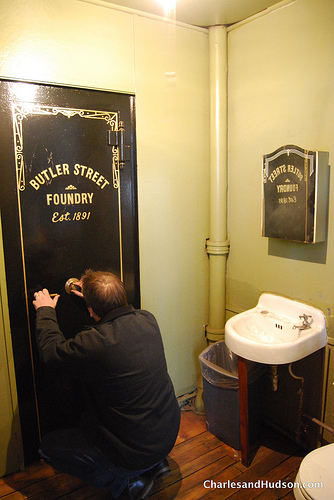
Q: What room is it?
A: It is a bathroom.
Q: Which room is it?
A: It is a bathroom.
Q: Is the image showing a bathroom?
A: Yes, it is showing a bathroom.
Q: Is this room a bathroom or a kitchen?
A: It is a bathroom.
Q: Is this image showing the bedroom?
A: No, the picture is showing the bathroom.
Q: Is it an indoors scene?
A: Yes, it is indoors.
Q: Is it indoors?
A: Yes, it is indoors.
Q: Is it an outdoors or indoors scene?
A: It is indoors.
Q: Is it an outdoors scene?
A: No, it is indoors.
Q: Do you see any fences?
A: No, there are no fences.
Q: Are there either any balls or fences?
A: No, there are no fences or balls.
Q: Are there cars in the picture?
A: No, there are no cars.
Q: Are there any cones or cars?
A: No, there are no cars or cones.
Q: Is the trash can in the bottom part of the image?
A: Yes, the trash can is in the bottom of the image.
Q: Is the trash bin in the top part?
A: No, the trash bin is in the bottom of the image.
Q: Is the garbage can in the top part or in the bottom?
A: The garbage can is in the bottom of the image.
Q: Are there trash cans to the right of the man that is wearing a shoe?
A: Yes, there is a trash can to the right of the man.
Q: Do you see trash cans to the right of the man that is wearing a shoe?
A: Yes, there is a trash can to the right of the man.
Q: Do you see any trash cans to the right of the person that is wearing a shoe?
A: Yes, there is a trash can to the right of the man.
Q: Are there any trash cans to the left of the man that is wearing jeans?
A: No, the trash can is to the right of the man.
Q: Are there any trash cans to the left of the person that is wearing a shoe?
A: No, the trash can is to the right of the man.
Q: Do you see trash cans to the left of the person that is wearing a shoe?
A: No, the trash can is to the right of the man.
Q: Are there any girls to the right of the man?
A: No, there is a trash can to the right of the man.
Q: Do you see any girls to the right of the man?
A: No, there is a trash can to the right of the man.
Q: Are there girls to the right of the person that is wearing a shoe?
A: No, there is a trash can to the right of the man.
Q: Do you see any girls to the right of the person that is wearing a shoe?
A: No, there is a trash can to the right of the man.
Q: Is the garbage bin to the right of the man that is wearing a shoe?
A: Yes, the garbage bin is to the right of the man.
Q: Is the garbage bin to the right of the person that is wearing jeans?
A: Yes, the garbage bin is to the right of the man.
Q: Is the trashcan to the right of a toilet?
A: No, the trashcan is to the right of the man.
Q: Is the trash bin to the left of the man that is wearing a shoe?
A: No, the trash bin is to the right of the man.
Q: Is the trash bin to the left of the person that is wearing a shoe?
A: No, the trash bin is to the right of the man.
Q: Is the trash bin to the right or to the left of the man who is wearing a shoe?
A: The trash bin is to the right of the man.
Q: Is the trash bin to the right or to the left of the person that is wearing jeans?
A: The trash bin is to the right of the man.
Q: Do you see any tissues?
A: No, there are no tissues.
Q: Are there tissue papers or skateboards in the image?
A: No, there are no tissue papers or skateboards.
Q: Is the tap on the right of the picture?
A: Yes, the tap is on the right of the image.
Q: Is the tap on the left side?
A: No, the tap is on the right of the image.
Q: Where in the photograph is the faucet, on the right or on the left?
A: The faucet is on the right of the image.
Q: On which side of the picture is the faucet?
A: The faucet is on the right of the image.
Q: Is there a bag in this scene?
A: Yes, there is a bag.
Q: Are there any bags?
A: Yes, there is a bag.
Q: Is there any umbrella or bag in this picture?
A: Yes, there is a bag.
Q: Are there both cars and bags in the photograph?
A: No, there is a bag but no cars.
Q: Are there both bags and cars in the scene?
A: No, there is a bag but no cars.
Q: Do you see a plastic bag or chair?
A: Yes, there is a plastic bag.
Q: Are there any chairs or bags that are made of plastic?
A: Yes, the bag is made of plastic.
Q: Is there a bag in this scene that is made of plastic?
A: Yes, there is a bag that is made of plastic.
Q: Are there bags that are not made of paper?
A: Yes, there is a bag that is made of plastic.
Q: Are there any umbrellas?
A: No, there are no umbrellas.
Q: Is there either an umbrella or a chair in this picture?
A: No, there are no umbrellas or chairs.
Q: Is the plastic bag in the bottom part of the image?
A: Yes, the bag is in the bottom of the image.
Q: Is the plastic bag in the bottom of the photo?
A: Yes, the bag is in the bottom of the image.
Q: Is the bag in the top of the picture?
A: No, the bag is in the bottom of the image.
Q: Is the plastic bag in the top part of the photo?
A: No, the bag is in the bottom of the image.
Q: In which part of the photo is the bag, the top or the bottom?
A: The bag is in the bottom of the image.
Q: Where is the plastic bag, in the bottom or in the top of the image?
A: The bag is in the bottom of the image.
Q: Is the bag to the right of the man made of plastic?
A: Yes, the bag is made of plastic.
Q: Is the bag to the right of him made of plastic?
A: Yes, the bag is made of plastic.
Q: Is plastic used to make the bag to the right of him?
A: Yes, the bag is made of plastic.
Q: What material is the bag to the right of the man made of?
A: The bag is made of plastic.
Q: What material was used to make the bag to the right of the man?
A: The bag is made of plastic.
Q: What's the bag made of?
A: The bag is made of plastic.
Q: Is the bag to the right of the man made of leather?
A: No, the bag is made of plastic.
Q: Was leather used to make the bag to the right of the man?
A: No, the bag is made of plastic.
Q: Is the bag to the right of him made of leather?
A: No, the bag is made of plastic.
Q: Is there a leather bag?
A: No, there is a bag but it is made of plastic.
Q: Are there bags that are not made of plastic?
A: No, there is a bag but it is made of plastic.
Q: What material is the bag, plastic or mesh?
A: The bag is made of plastic.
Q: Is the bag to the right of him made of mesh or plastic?
A: The bag is made of plastic.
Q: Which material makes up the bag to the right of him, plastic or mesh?
A: The bag is made of plastic.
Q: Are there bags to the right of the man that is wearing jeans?
A: Yes, there is a bag to the right of the man.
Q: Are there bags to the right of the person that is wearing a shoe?
A: Yes, there is a bag to the right of the man.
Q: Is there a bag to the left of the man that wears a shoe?
A: No, the bag is to the right of the man.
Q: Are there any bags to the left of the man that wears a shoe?
A: No, the bag is to the right of the man.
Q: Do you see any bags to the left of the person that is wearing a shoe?
A: No, the bag is to the right of the man.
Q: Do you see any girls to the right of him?
A: No, there is a bag to the right of the man.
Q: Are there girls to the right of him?
A: No, there is a bag to the right of the man.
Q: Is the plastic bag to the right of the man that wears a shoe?
A: Yes, the bag is to the right of the man.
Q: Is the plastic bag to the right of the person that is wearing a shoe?
A: Yes, the bag is to the right of the man.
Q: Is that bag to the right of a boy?
A: No, the bag is to the right of the man.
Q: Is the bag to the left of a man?
A: No, the bag is to the right of a man.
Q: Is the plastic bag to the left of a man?
A: No, the bag is to the right of a man.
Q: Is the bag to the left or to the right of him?
A: The bag is to the right of the man.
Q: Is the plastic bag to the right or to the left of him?
A: The bag is to the right of the man.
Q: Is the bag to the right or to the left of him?
A: The bag is to the right of the man.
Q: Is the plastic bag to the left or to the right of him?
A: The bag is to the right of the man.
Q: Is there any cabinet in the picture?
A: Yes, there is a cabinet.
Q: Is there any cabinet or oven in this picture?
A: Yes, there is a cabinet.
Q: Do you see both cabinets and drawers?
A: No, there is a cabinet but no drawers.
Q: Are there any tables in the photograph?
A: No, there are no tables.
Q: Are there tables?
A: No, there are no tables.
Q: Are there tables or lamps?
A: No, there are no tables or lamps.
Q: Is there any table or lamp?
A: No, there are no tables or lamps.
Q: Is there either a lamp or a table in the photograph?
A: No, there are no tables or lamps.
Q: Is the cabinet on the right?
A: Yes, the cabinet is on the right of the image.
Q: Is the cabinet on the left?
A: No, the cabinet is on the right of the image.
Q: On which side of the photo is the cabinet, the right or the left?
A: The cabinet is on the right of the image.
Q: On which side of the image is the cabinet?
A: The cabinet is on the right of the image.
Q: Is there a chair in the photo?
A: No, there are no chairs.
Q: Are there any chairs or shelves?
A: No, there are no chairs or shelves.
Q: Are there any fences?
A: No, there are no fences.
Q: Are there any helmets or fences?
A: No, there are no fences or helmets.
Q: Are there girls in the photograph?
A: No, there are no girls.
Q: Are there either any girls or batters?
A: No, there are no girls or batters.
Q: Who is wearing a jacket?
A: The man is wearing a jacket.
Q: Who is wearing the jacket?
A: The man is wearing a jacket.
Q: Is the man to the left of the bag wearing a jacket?
A: Yes, the man is wearing a jacket.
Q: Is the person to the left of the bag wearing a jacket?
A: Yes, the man is wearing a jacket.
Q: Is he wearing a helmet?
A: No, the man is wearing a jacket.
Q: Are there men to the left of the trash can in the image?
A: Yes, there is a man to the left of the trash can.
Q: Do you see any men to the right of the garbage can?
A: No, the man is to the left of the garbage can.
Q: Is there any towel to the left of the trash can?
A: No, there is a man to the left of the trash can.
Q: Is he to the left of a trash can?
A: Yes, the man is to the left of a trash can.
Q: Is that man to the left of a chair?
A: No, the man is to the left of a trash can.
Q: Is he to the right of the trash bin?
A: No, the man is to the left of the trash bin.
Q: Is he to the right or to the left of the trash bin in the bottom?
A: The man is to the left of the garbage bin.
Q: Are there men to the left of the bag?
A: Yes, there is a man to the left of the bag.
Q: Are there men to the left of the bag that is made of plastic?
A: Yes, there is a man to the left of the bag.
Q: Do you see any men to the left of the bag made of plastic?
A: Yes, there is a man to the left of the bag.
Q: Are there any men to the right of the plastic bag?
A: No, the man is to the left of the bag.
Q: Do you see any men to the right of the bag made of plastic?
A: No, the man is to the left of the bag.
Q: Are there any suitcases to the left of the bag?
A: No, there is a man to the left of the bag.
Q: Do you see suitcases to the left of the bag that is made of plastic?
A: No, there is a man to the left of the bag.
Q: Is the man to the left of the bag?
A: Yes, the man is to the left of the bag.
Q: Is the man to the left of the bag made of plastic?
A: Yes, the man is to the left of the bag.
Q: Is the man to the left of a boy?
A: No, the man is to the left of the bag.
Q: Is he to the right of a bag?
A: No, the man is to the left of a bag.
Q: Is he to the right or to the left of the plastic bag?
A: The man is to the left of the bag.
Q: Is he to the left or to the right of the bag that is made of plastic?
A: The man is to the left of the bag.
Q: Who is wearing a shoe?
A: The man is wearing a shoe.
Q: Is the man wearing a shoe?
A: Yes, the man is wearing a shoe.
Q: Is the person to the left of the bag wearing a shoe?
A: Yes, the man is wearing a shoe.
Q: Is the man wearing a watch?
A: No, the man is wearing a shoe.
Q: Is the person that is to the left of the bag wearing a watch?
A: No, the man is wearing a shoe.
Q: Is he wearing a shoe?
A: Yes, the man is wearing a shoe.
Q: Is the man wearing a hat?
A: No, the man is wearing a shoe.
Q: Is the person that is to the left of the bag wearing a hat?
A: No, the man is wearing a shoe.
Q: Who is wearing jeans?
A: The man is wearing jeans.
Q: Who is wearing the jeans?
A: The man is wearing jeans.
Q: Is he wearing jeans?
A: Yes, the man is wearing jeans.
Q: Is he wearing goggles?
A: No, the man is wearing jeans.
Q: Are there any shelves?
A: No, there are no shelves.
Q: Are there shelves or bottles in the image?
A: No, there are no shelves or bottles.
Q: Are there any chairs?
A: No, there are no chairs.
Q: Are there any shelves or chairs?
A: No, there are no chairs or shelves.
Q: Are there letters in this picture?
A: Yes, there are letters.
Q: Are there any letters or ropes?
A: Yes, there are letters.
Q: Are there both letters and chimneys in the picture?
A: No, there are letters but no chimneys.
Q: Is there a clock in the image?
A: No, there are no clocks.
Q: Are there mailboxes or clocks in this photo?
A: No, there are no clocks or mailboxes.